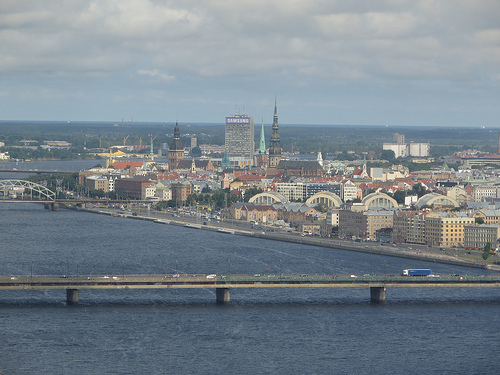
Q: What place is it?
A: It is a city.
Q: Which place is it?
A: It is a city.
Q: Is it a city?
A: Yes, it is a city.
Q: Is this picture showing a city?
A: Yes, it is showing a city.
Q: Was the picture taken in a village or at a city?
A: It was taken at a city.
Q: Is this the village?
A: No, it is the city.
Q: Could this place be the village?
A: No, it is the city.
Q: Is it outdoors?
A: Yes, it is outdoors.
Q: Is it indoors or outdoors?
A: It is outdoors.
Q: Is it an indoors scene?
A: No, it is outdoors.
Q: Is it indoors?
A: No, it is outdoors.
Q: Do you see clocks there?
A: No, there are no clocks.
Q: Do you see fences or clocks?
A: No, there are no clocks or fences.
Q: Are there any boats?
A: No, there are no boats.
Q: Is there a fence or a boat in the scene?
A: No, there are no boats or fences.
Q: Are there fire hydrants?
A: No, there are no fire hydrants.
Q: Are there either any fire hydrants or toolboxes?
A: No, there are no fire hydrants or toolboxes.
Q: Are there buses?
A: No, there are no buses.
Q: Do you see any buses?
A: No, there are no buses.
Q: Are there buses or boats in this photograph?
A: No, there are no buses or boats.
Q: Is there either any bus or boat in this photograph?
A: No, there are no buses or boats.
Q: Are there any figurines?
A: No, there are no figurines.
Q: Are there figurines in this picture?
A: No, there are no figurines.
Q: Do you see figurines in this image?
A: No, there are no figurines.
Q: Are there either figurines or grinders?
A: No, there are no figurines or grinders.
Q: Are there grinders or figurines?
A: No, there are no figurines or grinders.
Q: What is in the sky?
A: The clouds are in the sky.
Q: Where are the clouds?
A: The clouds are in the sky.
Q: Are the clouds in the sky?
A: Yes, the clouds are in the sky.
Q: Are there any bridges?
A: Yes, there is a bridge.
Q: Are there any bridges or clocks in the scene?
A: Yes, there is a bridge.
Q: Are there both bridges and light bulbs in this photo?
A: No, there is a bridge but no light bulbs.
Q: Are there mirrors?
A: No, there are no mirrors.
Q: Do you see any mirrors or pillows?
A: No, there are no mirrors or pillows.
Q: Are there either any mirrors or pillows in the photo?
A: No, there are no mirrors or pillows.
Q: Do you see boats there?
A: No, there are no boats.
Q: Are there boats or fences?
A: No, there are no boats or fences.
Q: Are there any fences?
A: No, there are no fences.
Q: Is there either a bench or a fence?
A: No, there are no fences or benches.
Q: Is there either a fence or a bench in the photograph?
A: No, there are no fences or benches.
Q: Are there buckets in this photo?
A: No, there are no buckets.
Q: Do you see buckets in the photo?
A: No, there are no buckets.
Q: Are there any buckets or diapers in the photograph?
A: No, there are no buckets or diapers.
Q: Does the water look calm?
A: Yes, the water is calm.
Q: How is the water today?
A: The water is calm.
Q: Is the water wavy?
A: No, the water is calm.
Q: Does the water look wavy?
A: No, the water is calm.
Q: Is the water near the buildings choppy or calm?
A: The water is calm.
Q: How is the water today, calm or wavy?
A: The water is calm.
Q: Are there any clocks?
A: No, there are no clocks.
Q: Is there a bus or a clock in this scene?
A: No, there are no clocks or buses.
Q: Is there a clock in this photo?
A: No, there are no clocks.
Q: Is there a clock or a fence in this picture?
A: No, there are no clocks or fences.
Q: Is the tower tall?
A: Yes, the tower is tall.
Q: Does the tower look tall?
A: Yes, the tower is tall.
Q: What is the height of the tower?
A: The tower is tall.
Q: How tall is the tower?
A: The tower is tall.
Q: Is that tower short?
A: No, the tower is tall.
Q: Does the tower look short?
A: No, the tower is tall.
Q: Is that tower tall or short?
A: The tower is tall.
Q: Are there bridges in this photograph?
A: Yes, there is a bridge.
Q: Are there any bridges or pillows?
A: Yes, there is a bridge.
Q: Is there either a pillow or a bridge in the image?
A: Yes, there is a bridge.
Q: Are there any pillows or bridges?
A: Yes, there is a bridge.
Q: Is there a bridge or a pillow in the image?
A: Yes, there is a bridge.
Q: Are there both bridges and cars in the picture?
A: Yes, there are both a bridge and a car.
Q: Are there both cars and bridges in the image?
A: Yes, there are both a bridge and a car.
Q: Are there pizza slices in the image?
A: No, there are no pizza slices.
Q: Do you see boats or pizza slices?
A: No, there are no pizza slices or boats.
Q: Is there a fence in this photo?
A: No, there are no fences.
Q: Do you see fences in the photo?
A: No, there are no fences.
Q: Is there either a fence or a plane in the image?
A: No, there are no fences or airplanes.